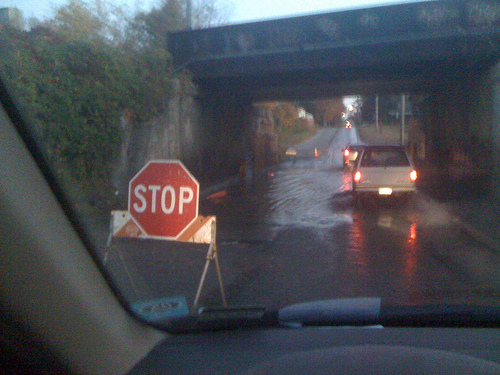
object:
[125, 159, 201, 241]
stop sign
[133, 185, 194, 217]
letters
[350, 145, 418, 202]
car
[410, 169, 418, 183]
tail light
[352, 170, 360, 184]
tail light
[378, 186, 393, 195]
license plate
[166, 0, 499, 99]
bridge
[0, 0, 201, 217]
shrub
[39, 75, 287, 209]
wall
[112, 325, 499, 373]
dashboard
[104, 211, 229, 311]
barrier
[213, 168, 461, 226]
puddle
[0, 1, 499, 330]
window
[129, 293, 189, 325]
sticker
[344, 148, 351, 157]
tail light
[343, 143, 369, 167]
car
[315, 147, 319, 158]
traffic cone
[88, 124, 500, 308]
road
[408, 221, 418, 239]
tail light reflectio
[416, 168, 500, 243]
sidewalk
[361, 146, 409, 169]
window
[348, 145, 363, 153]
window